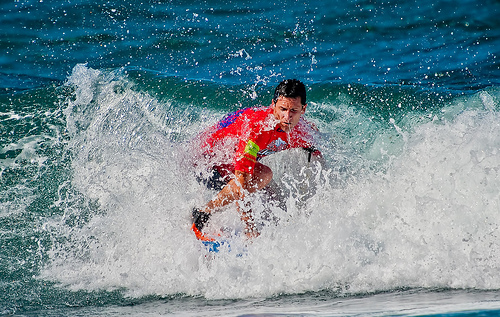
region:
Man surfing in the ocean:
[160, 64, 375, 292]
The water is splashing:
[65, 113, 198, 261]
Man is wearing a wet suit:
[199, 65, 276, 219]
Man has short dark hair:
[255, 60, 322, 127]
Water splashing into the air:
[187, 7, 289, 74]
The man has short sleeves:
[201, 76, 314, 231]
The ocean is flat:
[157, 12, 276, 54]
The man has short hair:
[271, 71, 324, 126]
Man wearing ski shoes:
[175, 176, 226, 262]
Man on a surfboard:
[168, 213, 258, 269]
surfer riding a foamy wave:
[177, 74, 336, 249]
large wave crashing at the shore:
[345, 73, 495, 308]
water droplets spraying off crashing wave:
[177, 0, 354, 93]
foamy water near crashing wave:
[0, 85, 67, 218]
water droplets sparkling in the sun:
[253, 7, 480, 74]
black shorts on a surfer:
[174, 154, 271, 202]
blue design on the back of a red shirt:
[209, 101, 250, 136]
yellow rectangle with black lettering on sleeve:
[233, 130, 260, 168]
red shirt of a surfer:
[200, 105, 332, 180]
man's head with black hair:
[267, 75, 317, 137]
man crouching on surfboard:
[163, 78, 350, 253]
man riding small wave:
[175, 83, 365, 268]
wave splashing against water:
[58, 60, 399, 261]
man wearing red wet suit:
[175, 90, 333, 206]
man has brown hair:
[260, 74, 318, 137]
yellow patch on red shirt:
[244, 136, 264, 161]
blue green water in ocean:
[201, 41, 343, 80]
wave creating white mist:
[372, 113, 497, 305]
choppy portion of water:
[219, 43, 431, 90]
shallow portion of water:
[328, 292, 467, 315]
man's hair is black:
[256, 68, 306, 108]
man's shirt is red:
[181, 91, 281, 163]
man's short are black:
[189, 161, 234, 188]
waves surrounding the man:
[51, 50, 497, 300]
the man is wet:
[164, 68, 351, 234]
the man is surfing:
[169, 67, 344, 256]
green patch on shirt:
[236, 140, 263, 163]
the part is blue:
[191, 237, 241, 264]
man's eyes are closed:
[257, 88, 308, 123]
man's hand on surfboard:
[231, 202, 266, 247]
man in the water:
[155, 53, 361, 244]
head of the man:
[261, 75, 321, 136]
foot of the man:
[171, 196, 216, 236]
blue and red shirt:
[215, 100, 270, 135]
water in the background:
[20, 10, 65, 55]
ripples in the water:
[391, 11, 456, 56]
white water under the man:
[401, 170, 438, 200]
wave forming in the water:
[66, 60, 137, 150]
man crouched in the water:
[175, 50, 330, 245]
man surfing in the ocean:
[130, 56, 340, 263]